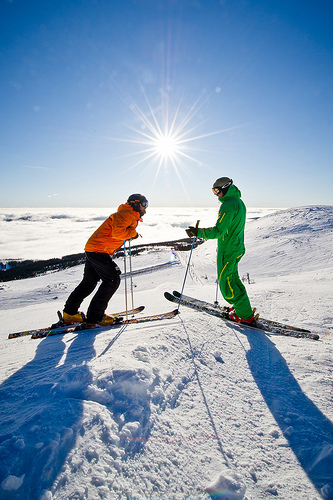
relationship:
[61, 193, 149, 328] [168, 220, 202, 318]
man leaning on pole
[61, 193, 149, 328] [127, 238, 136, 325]
man leaning on pole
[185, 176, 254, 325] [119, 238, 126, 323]
man leaning on pole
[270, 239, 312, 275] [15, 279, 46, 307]
snow on ground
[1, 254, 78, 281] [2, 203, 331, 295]
trees going up mountain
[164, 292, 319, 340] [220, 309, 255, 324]
ski on foot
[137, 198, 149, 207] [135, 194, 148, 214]
goggles on face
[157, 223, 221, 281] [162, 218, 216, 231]
pole on hand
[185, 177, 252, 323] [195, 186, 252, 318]
man wearing coveralls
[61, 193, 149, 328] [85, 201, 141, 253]
man wearing jacket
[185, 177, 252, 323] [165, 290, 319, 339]
man wearing skis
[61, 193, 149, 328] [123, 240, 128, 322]
man leaning on pole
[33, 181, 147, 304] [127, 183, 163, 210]
man wearing hat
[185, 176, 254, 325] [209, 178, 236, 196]
man wearing goggles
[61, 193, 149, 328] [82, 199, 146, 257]
man wears jacket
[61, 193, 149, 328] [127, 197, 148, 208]
man wearing goggles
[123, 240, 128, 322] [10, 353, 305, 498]
pole in snow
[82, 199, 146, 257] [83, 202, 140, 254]
jacket on body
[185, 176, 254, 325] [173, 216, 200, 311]
man holding ski pole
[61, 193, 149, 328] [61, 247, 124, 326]
man has pants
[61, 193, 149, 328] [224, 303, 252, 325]
man has ski boots